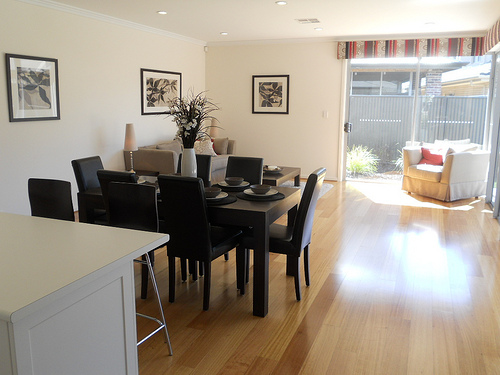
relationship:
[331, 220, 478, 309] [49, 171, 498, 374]
light reflecting on floor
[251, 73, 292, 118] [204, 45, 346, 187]
picture hanging on wall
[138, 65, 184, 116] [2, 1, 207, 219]
picture hanging on wall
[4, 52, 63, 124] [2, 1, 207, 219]
picture hanging on wall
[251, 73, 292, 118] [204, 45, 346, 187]
picture on wall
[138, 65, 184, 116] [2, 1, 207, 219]
picture on wall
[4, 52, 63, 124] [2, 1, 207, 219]
picture on wall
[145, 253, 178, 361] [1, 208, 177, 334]
leg near counter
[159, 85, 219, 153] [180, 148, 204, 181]
flower arrangement in vase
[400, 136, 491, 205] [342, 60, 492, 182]
chair in front of sliding doors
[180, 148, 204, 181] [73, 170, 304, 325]
vase on table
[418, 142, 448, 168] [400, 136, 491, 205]
pillow on a chair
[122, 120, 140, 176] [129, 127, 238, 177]
lamp beside couch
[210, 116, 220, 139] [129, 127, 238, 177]
lamp beside couch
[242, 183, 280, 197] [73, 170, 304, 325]
china setting on table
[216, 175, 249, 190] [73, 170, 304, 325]
china setting on table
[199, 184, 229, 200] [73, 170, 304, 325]
china setting on table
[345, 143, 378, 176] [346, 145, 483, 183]
plant in yard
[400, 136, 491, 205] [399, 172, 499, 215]
chair in corner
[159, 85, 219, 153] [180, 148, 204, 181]
flower arrangement in a vase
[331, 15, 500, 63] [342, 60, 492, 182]
valence over windows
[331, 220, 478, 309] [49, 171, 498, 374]
reflection on floor